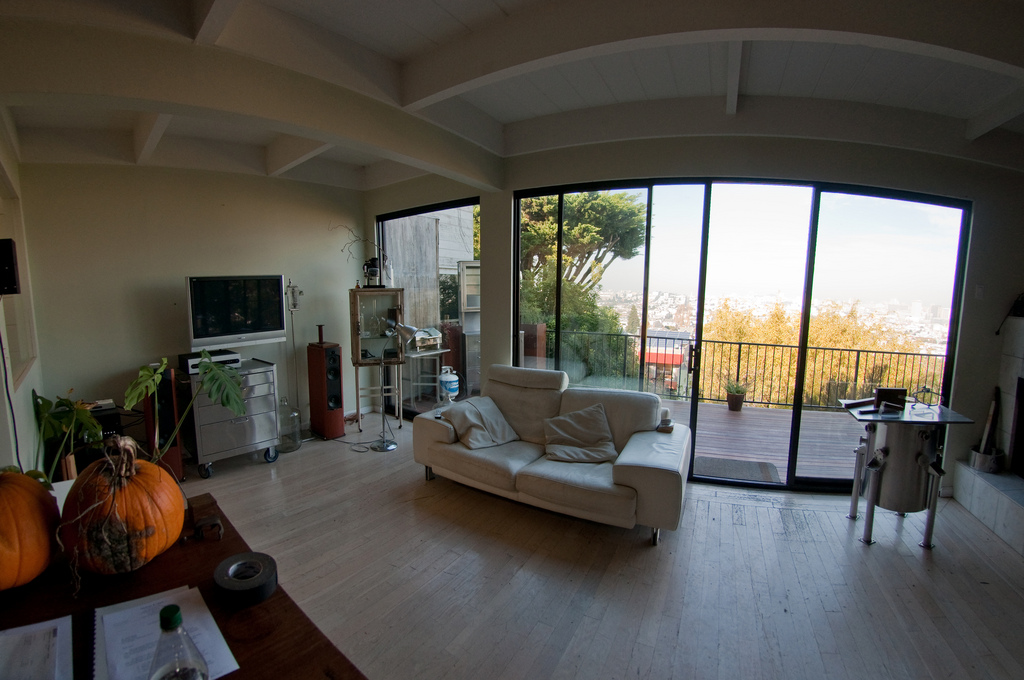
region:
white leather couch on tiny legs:
[408, 358, 691, 549]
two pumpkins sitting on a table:
[2, 432, 186, 582]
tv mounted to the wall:
[175, 266, 296, 347]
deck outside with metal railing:
[495, 313, 957, 492]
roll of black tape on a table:
[215, 543, 280, 605]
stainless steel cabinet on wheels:
[179, 353, 288, 481]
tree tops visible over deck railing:
[697, 290, 935, 404]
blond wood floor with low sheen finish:
[157, 410, 1020, 676]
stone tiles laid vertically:
[947, 451, 1021, 560]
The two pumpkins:
[4, 434, 194, 589]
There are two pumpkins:
[5, 427, 202, 587]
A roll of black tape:
[213, 538, 289, 599]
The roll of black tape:
[205, 542, 295, 597]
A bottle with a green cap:
[134, 601, 217, 674]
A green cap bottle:
[129, 600, 218, 673]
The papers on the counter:
[2, 581, 238, 674]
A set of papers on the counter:
[4, 581, 249, 674]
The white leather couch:
[403, 351, 720, 551]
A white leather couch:
[406, 355, 705, 536]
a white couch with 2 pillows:
[413, 353, 702, 559]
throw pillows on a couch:
[442, 383, 621, 473]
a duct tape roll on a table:
[211, 543, 284, 608]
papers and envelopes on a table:
[5, 578, 243, 677]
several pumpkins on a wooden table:
[0, 439, 207, 621]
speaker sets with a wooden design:
[303, 313, 355, 465]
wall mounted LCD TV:
[168, 256, 299, 358]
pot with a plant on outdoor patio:
[710, 372, 756, 417]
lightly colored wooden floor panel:
[509, 576, 652, 675]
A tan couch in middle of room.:
[409, 350, 700, 522]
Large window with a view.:
[531, 183, 959, 469]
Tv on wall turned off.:
[172, 276, 312, 359]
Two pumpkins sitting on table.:
[6, 432, 197, 587]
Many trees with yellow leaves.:
[709, 309, 929, 404]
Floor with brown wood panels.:
[398, 533, 877, 666]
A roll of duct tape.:
[209, 549, 289, 619]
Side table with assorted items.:
[837, 382, 955, 566]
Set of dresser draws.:
[187, 360, 289, 469]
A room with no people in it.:
[32, 172, 988, 651]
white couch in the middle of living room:
[412, 359, 689, 549]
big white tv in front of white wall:
[183, 263, 285, 361]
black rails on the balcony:
[617, 325, 959, 405]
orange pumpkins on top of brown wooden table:
[1, 428, 191, 591]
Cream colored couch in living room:
[412, 359, 697, 559]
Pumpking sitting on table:
[59, 431, 192, 578]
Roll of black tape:
[207, 542, 284, 612]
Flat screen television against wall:
[179, 264, 301, 359]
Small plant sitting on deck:
[721, 372, 756, 408]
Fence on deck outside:
[589, 322, 950, 415]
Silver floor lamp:
[369, 314, 411, 458]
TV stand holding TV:
[184, 355, 292, 479]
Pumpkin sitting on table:
[1, 460, 68, 598]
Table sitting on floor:
[842, 381, 975, 560]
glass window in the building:
[371, 207, 438, 426]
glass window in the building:
[431, 198, 477, 405]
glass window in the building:
[516, 188, 551, 369]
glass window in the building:
[560, 179, 643, 385]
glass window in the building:
[646, 179, 694, 461]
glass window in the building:
[792, 188, 947, 499]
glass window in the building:
[514, 191, 556, 365]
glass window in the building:
[392, 339, 454, 410]